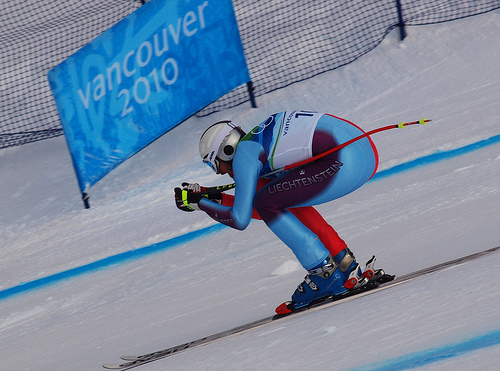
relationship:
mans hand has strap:
[183, 179, 209, 196] [178, 195, 201, 216]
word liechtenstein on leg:
[256, 158, 357, 196] [277, 221, 331, 280]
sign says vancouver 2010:
[30, 16, 264, 114] [72, 0, 222, 123]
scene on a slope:
[125, 90, 469, 292] [322, 74, 438, 110]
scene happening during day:
[125, 90, 469, 292] [20, 18, 471, 238]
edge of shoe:
[290, 293, 299, 309] [296, 256, 346, 297]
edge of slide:
[290, 293, 299, 309] [483, 250, 498, 259]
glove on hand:
[178, 181, 208, 204] [172, 189, 207, 208]